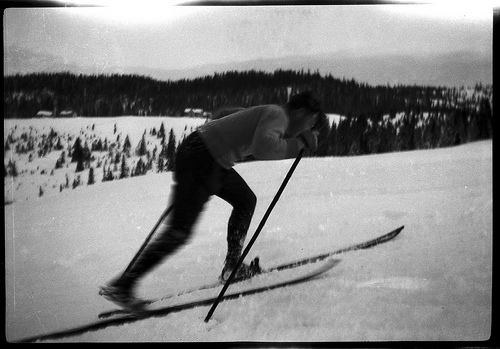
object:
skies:
[8, 258, 341, 344]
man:
[97, 91, 327, 307]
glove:
[302, 131, 320, 151]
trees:
[3, 123, 192, 206]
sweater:
[195, 105, 304, 170]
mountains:
[2, 68, 492, 118]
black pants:
[105, 130, 257, 291]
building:
[36, 109, 72, 116]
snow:
[60, 110, 72, 114]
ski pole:
[204, 148, 306, 323]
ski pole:
[119, 203, 176, 280]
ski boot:
[99, 257, 262, 313]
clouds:
[0, 0, 490, 86]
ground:
[1, 114, 500, 347]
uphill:
[3, 139, 491, 343]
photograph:
[0, 0, 500, 349]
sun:
[59, 0, 207, 26]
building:
[184, 108, 213, 117]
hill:
[0, 115, 492, 342]